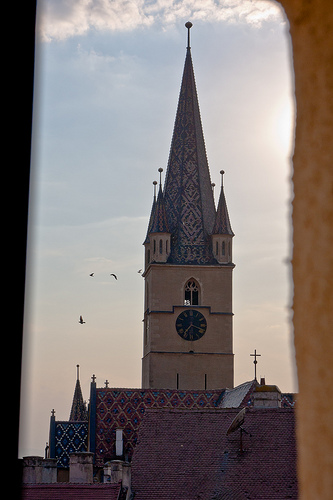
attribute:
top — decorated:
[122, 23, 258, 272]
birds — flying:
[62, 259, 124, 344]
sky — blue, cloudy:
[36, 28, 135, 365]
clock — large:
[174, 305, 210, 345]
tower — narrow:
[137, 38, 233, 385]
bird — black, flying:
[70, 302, 95, 338]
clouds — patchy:
[36, 2, 273, 57]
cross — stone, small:
[246, 346, 261, 389]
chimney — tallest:
[62, 451, 97, 493]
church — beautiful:
[72, 268, 287, 474]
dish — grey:
[220, 405, 261, 431]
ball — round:
[182, 21, 196, 31]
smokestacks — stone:
[29, 460, 127, 476]